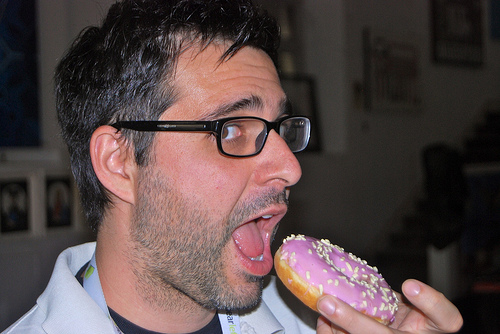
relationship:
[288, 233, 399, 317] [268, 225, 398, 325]
frosting on donut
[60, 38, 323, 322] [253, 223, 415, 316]
man with doughnut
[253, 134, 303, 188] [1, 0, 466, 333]
nose on man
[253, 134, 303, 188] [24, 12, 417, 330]
nose on man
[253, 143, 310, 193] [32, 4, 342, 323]
nose on man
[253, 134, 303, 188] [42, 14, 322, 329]
nose on man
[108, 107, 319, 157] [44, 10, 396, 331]
glasses are on man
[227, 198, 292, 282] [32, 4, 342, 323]
mouth on man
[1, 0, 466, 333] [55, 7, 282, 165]
man with hair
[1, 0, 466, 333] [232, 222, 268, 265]
man hanging out h tongue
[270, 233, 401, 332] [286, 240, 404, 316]
donut with sprinkles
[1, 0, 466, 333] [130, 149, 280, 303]
man with beard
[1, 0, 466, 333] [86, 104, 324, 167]
man with glasses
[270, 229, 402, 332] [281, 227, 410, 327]
donut with frosting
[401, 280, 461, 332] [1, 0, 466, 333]
finger of man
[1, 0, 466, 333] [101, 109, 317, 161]
man with glasses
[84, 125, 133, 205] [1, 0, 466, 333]
ear of man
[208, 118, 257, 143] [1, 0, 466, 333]
eye of man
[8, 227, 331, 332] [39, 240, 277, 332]
collar of shirt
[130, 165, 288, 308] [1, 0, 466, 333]
beard on a man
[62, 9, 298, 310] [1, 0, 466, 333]
head on a man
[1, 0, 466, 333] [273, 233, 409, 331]
man eating a donut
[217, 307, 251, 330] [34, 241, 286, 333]
name on collar